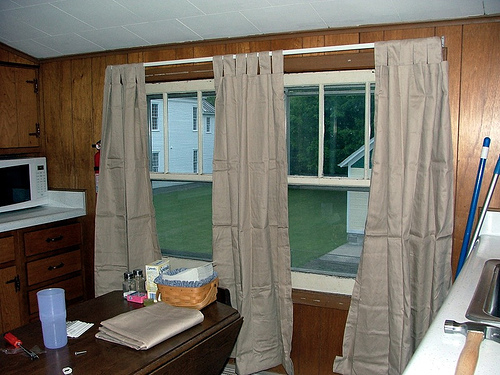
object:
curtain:
[208, 48, 295, 374]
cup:
[34, 288, 69, 349]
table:
[0, 287, 243, 374]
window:
[144, 174, 219, 261]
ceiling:
[0, 0, 499, 61]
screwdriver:
[3, 333, 41, 360]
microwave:
[0, 155, 47, 216]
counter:
[0, 205, 85, 237]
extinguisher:
[91, 138, 104, 194]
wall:
[36, 15, 499, 373]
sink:
[464, 258, 498, 324]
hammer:
[441, 318, 499, 374]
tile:
[75, 24, 153, 52]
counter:
[401, 210, 499, 375]